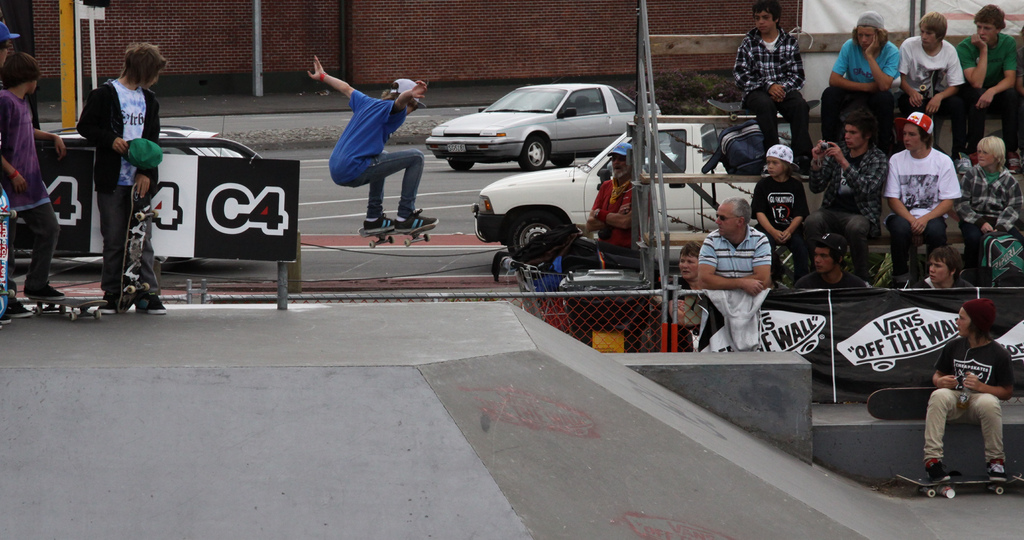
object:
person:
[895, 299, 1012, 497]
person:
[907, 247, 976, 289]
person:
[796, 233, 868, 288]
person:
[698, 198, 774, 354]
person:
[679, 241, 701, 325]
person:
[807, 112, 890, 281]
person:
[885, 110, 964, 282]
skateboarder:
[307, 55, 439, 248]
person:
[958, 136, 1021, 268]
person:
[751, 143, 809, 282]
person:
[803, 121, 886, 276]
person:
[955, 4, 1023, 151]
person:
[900, 11, 968, 155]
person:
[821, 11, 901, 136]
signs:
[759, 307, 961, 372]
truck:
[473, 115, 824, 263]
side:
[504, 249, 792, 353]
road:
[5, 108, 522, 281]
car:
[425, 83, 661, 170]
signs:
[43, 147, 298, 262]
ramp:
[2, 301, 1021, 538]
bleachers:
[679, 5, 1022, 298]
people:
[677, 0, 1017, 288]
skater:
[923, 299, 1016, 483]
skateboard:
[893, 473, 1021, 500]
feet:
[925, 459, 1008, 483]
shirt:
[698, 223, 772, 286]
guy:
[807, 120, 887, 285]